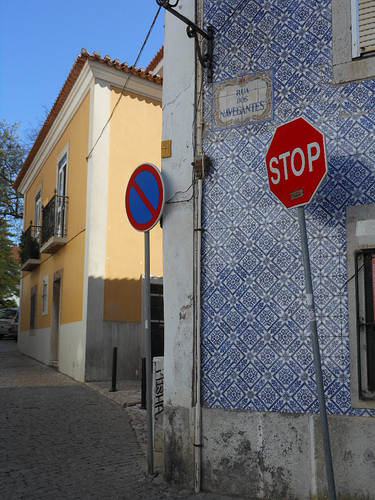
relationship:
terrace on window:
[40, 205, 65, 255] [59, 160, 66, 229]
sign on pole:
[262, 119, 329, 206] [291, 208, 336, 498]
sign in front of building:
[262, 119, 329, 206] [162, 3, 375, 498]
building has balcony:
[22, 86, 164, 350] [34, 194, 69, 255]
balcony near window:
[34, 194, 69, 255] [59, 160, 66, 229]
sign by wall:
[262, 119, 329, 206] [198, 6, 375, 410]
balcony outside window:
[34, 194, 69, 255] [59, 160, 66, 229]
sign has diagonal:
[124, 172, 163, 224] [132, 183, 159, 217]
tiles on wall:
[196, 6, 369, 416] [198, 6, 375, 410]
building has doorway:
[22, 86, 164, 350] [52, 273, 62, 369]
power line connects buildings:
[91, 1, 165, 161] [16, 8, 372, 494]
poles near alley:
[111, 350, 145, 404] [92, 274, 159, 379]